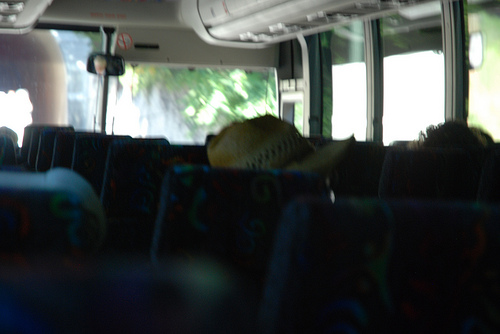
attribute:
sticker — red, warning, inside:
[112, 30, 137, 54]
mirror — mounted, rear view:
[82, 23, 131, 81]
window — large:
[0, 19, 278, 149]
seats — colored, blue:
[0, 123, 500, 333]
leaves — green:
[82, 19, 283, 140]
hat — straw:
[203, 112, 356, 179]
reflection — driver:
[94, 55, 118, 75]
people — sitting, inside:
[201, 107, 499, 213]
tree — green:
[115, 52, 276, 145]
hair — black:
[416, 115, 492, 151]